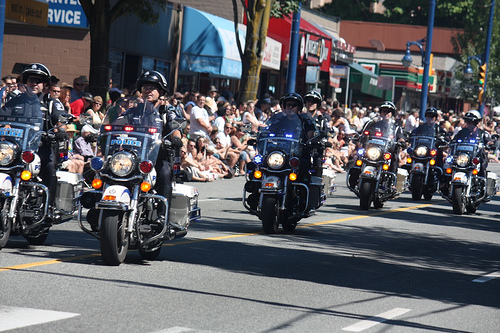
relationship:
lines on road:
[352, 287, 410, 332] [189, 287, 246, 330]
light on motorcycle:
[89, 155, 106, 172] [77, 102, 200, 265]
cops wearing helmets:
[109, 88, 491, 238] [263, 73, 425, 165]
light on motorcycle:
[240, 142, 304, 174] [217, 56, 357, 239]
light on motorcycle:
[138, 178, 151, 192] [72, 67, 207, 266]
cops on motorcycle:
[244, 91, 328, 216] [50, 65, 470, 263]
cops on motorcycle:
[79, 69, 190, 232] [77, 102, 200, 265]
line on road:
[171, 223, 261, 253] [6, 161, 497, 330]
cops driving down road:
[1, 62, 498, 266] [6, 161, 500, 333]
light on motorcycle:
[288, 172, 297, 179] [242, 108, 337, 232]